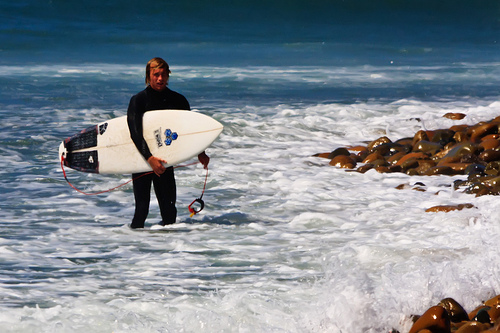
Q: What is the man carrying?
A: A white surf board.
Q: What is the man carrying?
A: Surfboard.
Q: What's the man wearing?
A: Wetsuit.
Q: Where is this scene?
A: Beach.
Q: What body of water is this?
A: Ocean.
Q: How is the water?
A: Foamy.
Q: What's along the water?
A: Rocks.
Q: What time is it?
A: 11:43 AM.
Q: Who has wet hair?
A: The man.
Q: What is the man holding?
A: A surfboard.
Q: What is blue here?
A: The water.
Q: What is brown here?
A: The rocks.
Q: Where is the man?
A: In the water.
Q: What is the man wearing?
A: A wet suit.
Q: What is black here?
A: The wetsuit.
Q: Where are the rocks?
A: On the shore.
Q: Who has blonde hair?
A: The surfer.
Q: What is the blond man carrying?
A: A surfboard.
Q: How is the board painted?
A: White.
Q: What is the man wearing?
A: A black wetsuit.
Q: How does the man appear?
A: Wet.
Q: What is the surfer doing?
A: Walking.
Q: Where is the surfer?
A: In the water.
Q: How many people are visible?
A: 1.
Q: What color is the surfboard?
A: White.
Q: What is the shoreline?
A: Rocks.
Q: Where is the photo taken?
A: Beach.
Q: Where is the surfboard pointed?
A: Right.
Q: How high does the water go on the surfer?
A: Knee deep.